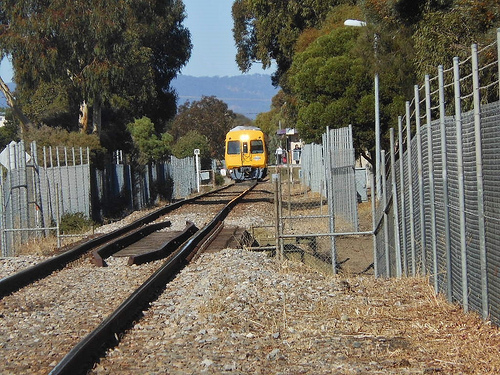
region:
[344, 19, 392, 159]
a street light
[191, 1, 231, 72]
the blue sky between the trees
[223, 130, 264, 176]
a yellow train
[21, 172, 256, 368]
train tracks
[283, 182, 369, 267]
a silver chain link fence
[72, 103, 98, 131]
the trunk of the trees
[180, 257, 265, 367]
some rocks along the tracks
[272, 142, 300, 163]
people standing on the side of the tracks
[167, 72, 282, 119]
a hill in the distance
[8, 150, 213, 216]
fence on the other side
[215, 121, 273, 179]
yellow train on track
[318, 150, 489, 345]
grey fence near track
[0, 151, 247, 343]
train on black track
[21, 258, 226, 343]
grey gravel between track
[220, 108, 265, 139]
white light on train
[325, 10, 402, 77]
light on grey pole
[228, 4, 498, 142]
green trees overhang track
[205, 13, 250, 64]
sky is blue and clear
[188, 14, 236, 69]
no clouds in sky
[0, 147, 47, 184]
diamond sign behind fence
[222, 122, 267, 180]
a yellow train coming down the tracks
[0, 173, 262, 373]
a set of train tracks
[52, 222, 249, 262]
a small wooden bridge over a sewer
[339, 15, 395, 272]
a light pole on the right side of the tracks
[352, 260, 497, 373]
dead dried grass near the fence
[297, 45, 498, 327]
a metal fence on the side of the tracks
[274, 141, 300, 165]
a few people standing in the distance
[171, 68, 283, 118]
a mountain range in the distance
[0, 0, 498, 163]
trees on either sides of the train tracks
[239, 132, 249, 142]
a light on the front of the train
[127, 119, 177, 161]
a tree along the fence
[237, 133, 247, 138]
the headlight on the train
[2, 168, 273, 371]
the train tracks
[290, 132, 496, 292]
a silver fence on the side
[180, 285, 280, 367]
rocks in the grass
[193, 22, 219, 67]
a blue sky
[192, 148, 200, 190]
a white pole on the side of the tracks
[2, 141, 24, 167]
the back of the sign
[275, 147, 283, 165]
a man in a white shirt